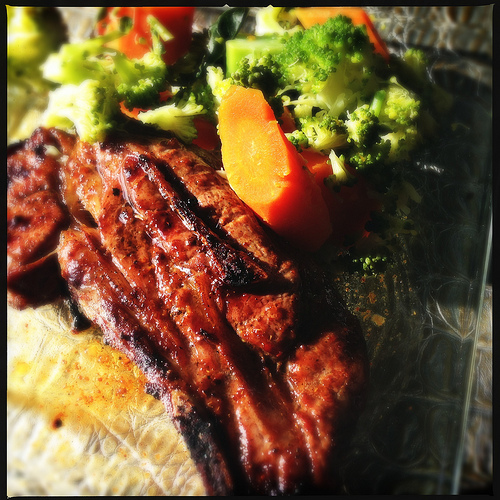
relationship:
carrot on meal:
[214, 85, 333, 247] [0, 0, 410, 491]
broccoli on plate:
[265, 11, 424, 180] [12, 7, 488, 496]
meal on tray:
[0, 0, 410, 491] [2, 0, 499, 498]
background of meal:
[358, 8, 495, 496] [0, 0, 410, 491]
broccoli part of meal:
[265, 11, 424, 180] [6, 9, 498, 496]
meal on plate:
[0, 0, 410, 491] [12, 7, 488, 496]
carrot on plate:
[214, 85, 333, 247] [12, 7, 488, 496]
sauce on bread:
[57, 335, 151, 415] [4, 301, 225, 498]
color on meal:
[74, 172, 113, 218] [0, 0, 410, 491]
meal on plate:
[0, 0, 410, 491] [266, 0, 496, 500]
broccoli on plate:
[34, 14, 173, 104] [266, 0, 496, 500]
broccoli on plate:
[6, 8, 436, 193] [12, 7, 488, 496]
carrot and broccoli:
[214, 85, 333, 247] [240, 19, 403, 181]